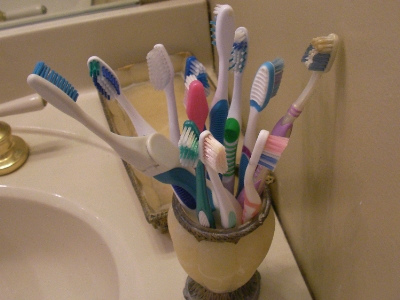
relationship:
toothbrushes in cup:
[29, 6, 341, 295] [151, 181, 303, 286]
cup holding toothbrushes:
[151, 181, 303, 286] [29, 6, 341, 295]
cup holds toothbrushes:
[151, 181, 303, 286] [29, 6, 341, 295]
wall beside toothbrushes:
[215, 3, 399, 267] [29, 6, 341, 295]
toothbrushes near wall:
[29, 6, 341, 295] [215, 3, 399, 267]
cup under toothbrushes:
[151, 181, 303, 286] [29, 6, 341, 295]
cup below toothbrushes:
[151, 181, 303, 286] [29, 6, 341, 295]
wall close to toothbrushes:
[215, 3, 399, 267] [29, 6, 341, 295]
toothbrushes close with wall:
[29, 6, 341, 295] [215, 3, 399, 267]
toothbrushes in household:
[29, 6, 341, 295] [9, 4, 399, 291]